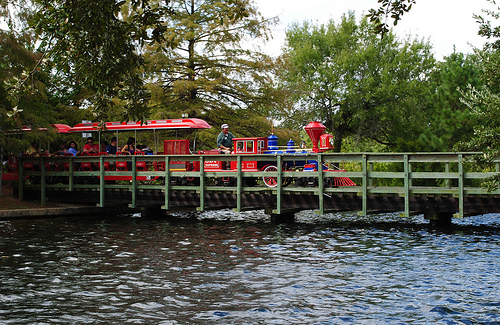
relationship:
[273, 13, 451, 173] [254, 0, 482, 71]
trees reaching up into sky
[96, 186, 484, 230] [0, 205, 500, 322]
bridge supports out of water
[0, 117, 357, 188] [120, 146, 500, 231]
train across bridge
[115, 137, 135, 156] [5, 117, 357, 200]
passenger on train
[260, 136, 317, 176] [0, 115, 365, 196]
engine of train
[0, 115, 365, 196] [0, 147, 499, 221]
train on bridge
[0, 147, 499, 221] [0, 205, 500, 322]
bridge over water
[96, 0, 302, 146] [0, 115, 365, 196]
tree next to train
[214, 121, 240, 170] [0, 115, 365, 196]
man driving train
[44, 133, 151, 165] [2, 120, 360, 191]
people ride train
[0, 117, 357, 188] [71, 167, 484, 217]
train moving on tracks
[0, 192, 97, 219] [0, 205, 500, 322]
bank at water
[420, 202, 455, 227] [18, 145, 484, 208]
bridge supports with track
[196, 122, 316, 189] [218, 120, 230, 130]
engine wearing cap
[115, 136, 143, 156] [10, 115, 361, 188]
passenger on train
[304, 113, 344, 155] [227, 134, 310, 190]
cowcatcher on engine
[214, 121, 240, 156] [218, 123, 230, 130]
man wearing cap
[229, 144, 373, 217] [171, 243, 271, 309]
bridge spanning water